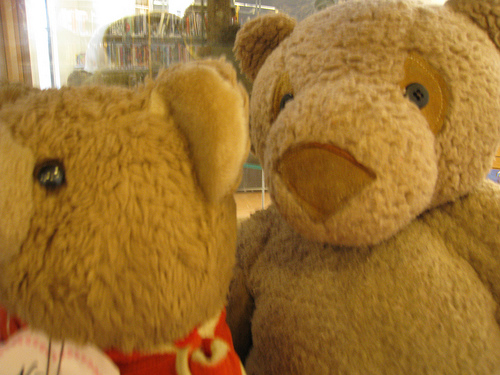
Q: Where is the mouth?
A: On bear.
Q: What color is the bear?
A: Brown.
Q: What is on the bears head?
A: Ear.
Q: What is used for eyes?
A: Buttons.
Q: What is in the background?
A: Many colors.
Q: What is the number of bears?
A: Two.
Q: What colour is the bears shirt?
A: Red and yellow.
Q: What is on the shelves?
A: Books.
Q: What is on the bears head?
A: Ear.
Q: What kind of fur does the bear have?
A: Matted.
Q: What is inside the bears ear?
A: Lighter fur.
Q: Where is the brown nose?
A: On the stuffed bear.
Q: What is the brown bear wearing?
A: No clothes.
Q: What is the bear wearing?
A: A red outfit.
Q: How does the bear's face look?
A: A long nose and mouth.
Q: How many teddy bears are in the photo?
A: Two.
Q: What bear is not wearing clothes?
A: The teddy bear on the right.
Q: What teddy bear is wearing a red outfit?
A: The bear on the left.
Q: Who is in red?
A: A teddy bear.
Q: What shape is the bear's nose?
A: Triangular.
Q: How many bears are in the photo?
A: Two.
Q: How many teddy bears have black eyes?
A: Two.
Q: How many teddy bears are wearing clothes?
A: One.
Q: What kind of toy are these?
A: Stuffed animals.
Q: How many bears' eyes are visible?
A: Three.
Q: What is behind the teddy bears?
A: A reflection in a window.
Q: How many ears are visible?
A: Three.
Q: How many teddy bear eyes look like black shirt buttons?
A: One.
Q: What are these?
A: Teddy bears.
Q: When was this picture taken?
A: During the day.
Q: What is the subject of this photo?
A: Two teddy bears.